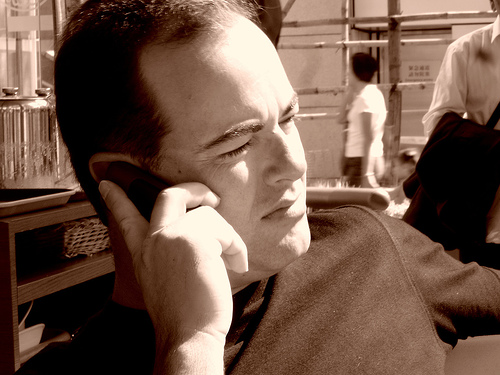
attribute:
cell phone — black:
[102, 159, 203, 225]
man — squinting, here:
[9, 1, 499, 374]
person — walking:
[341, 51, 389, 188]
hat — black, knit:
[350, 52, 379, 83]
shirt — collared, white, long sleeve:
[422, 11, 500, 246]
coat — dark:
[402, 110, 500, 266]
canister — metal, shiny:
[0, 86, 63, 190]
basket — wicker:
[29, 218, 113, 259]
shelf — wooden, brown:
[0, 198, 116, 374]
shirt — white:
[344, 83, 388, 158]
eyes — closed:
[215, 108, 302, 160]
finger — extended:
[97, 179, 150, 253]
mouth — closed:
[259, 188, 308, 220]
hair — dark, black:
[53, 0, 280, 230]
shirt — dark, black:
[13, 203, 500, 374]